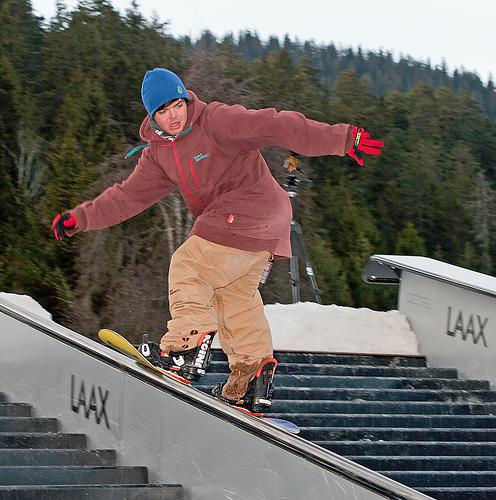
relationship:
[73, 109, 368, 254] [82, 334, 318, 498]
brown coat on boy on ledge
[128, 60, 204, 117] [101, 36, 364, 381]
blue wool cap on boy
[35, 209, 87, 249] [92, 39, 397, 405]
red glove on boy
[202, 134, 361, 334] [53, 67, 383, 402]
tripod behind a boy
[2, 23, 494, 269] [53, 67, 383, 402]
green forest behind boy